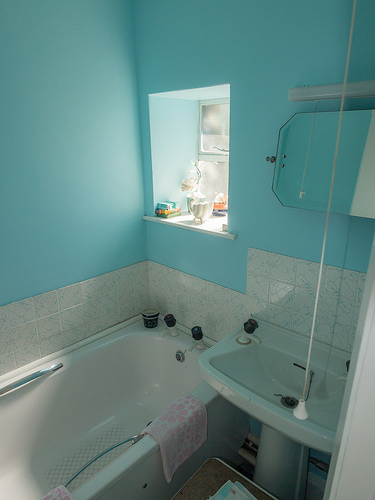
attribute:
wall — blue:
[5, 19, 140, 253]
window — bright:
[150, 93, 237, 238]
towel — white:
[135, 393, 223, 478]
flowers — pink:
[161, 407, 199, 447]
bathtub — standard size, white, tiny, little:
[7, 309, 252, 499]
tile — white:
[5, 248, 361, 358]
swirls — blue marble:
[52, 299, 94, 326]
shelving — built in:
[132, 194, 239, 249]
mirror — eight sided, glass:
[260, 99, 372, 225]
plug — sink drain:
[273, 387, 312, 410]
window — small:
[141, 80, 239, 234]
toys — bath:
[149, 193, 232, 231]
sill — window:
[140, 202, 234, 244]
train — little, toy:
[152, 194, 188, 219]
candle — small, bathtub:
[135, 305, 168, 337]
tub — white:
[5, 309, 259, 493]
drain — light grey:
[271, 390, 307, 412]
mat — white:
[27, 423, 144, 495]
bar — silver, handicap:
[1, 360, 71, 400]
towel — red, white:
[138, 388, 231, 483]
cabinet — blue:
[266, 114, 364, 222]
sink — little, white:
[195, 311, 362, 497]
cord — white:
[296, 3, 354, 431]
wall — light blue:
[3, 1, 367, 314]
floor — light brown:
[159, 453, 287, 498]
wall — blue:
[133, 3, 373, 303]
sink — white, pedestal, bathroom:
[202, 309, 353, 495]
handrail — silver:
[2, 361, 66, 402]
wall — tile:
[3, 248, 249, 372]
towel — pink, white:
[135, 387, 218, 489]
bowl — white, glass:
[185, 197, 222, 227]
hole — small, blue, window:
[146, 77, 235, 240]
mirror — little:
[262, 104, 373, 220]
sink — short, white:
[197, 307, 359, 487]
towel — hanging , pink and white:
[140, 389, 208, 481]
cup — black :
[142, 307, 161, 328]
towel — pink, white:
[142, 395, 213, 482]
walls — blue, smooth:
[3, 2, 150, 377]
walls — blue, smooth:
[136, 4, 371, 498]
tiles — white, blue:
[1, 239, 363, 383]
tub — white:
[5, 312, 277, 498]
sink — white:
[209, 314, 361, 459]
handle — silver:
[1, 356, 68, 394]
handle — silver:
[56, 422, 158, 493]